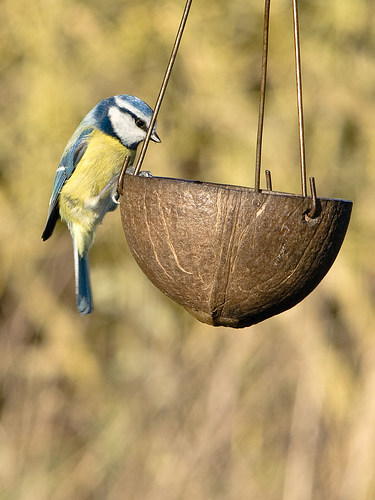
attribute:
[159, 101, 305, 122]
hangers — three and metal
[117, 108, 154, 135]
stripe — thin and black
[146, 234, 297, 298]
birdfeeder —  brown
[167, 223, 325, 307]
pot —  metallic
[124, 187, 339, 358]
feeder — brown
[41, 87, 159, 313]
bird — yellow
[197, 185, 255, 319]
patch — thick